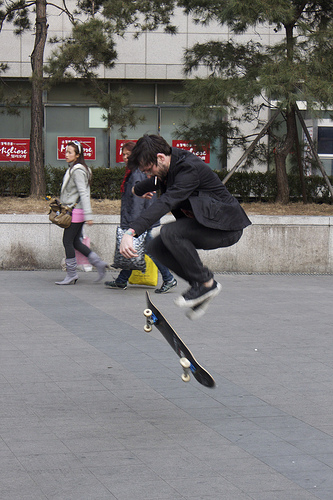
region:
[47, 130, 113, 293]
a person in the picture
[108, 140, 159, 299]
a person in the picture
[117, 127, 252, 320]
a person in the picture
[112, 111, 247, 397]
a person in the picture is skating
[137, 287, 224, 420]
the skate board is black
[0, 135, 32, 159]
a red sign in the background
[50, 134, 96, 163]
a red sign in the background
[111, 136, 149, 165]
a red sign in the background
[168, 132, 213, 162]
a red sign in the background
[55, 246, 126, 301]
the woman is wearing grey boots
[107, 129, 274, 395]
man riding a skateboard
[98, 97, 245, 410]
man doing a trick with the skateboard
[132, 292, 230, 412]
the skateboard is black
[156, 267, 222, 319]
the man is wearing black sneakers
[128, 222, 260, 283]
the man is wearing black jeans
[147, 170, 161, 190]
something in the man`s mouth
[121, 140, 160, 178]
the man is wearing glasses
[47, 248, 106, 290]
the woman`s boots are grey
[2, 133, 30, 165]
the sign is red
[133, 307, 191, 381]
the wheels are white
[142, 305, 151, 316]
White wheel on skateboard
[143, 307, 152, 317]
Round white wheel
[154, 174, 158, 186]
Cigarette in mouth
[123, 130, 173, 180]
Black hair on head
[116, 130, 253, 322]
Man in black blazer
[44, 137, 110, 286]
Young woman walking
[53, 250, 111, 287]
Young woman wearing grey heeled boots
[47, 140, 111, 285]
Young woman carrying brown purse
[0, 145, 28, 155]
White letters on sign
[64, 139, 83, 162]
White sunglasses on head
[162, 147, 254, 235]
The black jacket the guy is wearing.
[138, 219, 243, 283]
The black jeans the guy is wearing.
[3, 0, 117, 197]
The tall tree on the left.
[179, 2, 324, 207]
The tree on the right.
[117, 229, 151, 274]
The gray bag the lady is holding.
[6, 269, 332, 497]
The gray cement the people are on.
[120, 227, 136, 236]
The watch on the man's wrist.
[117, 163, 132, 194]
The red scarf the girl is wearing.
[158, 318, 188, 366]
The design on the bottom of the skateboard.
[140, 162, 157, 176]
The eyeglasses the man is wearing.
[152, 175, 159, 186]
The cigarette in the guy's mouth.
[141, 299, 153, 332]
The front wheels of the skateboard.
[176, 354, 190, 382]
The back wheels of the skateboard.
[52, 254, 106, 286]
The gray high heel boots the girl is wearing.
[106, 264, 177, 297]
The black sneakers the girl in the black jacket is wearing.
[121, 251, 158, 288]
The yellow bag the girl is holding.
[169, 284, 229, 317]
The black and white sneakers the guy on the skateboard is wearing.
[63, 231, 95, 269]
The pink bag the girl in the gray boots is carrying.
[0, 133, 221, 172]
The red signs on the windows of the building.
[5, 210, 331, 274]
The cement wall to the right of the women walking.